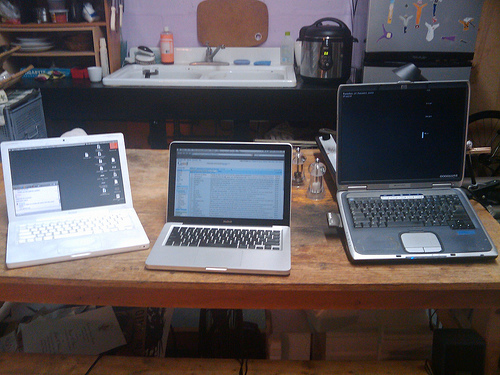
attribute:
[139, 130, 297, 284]
laptop — open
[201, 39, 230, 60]
faucet — silver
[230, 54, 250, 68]
soap — blue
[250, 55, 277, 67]
soap — blue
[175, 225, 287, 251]
keys — black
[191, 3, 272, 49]
cutting board — brown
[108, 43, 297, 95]
sink — white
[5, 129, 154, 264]
laptop — on, white, open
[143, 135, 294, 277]
laptop — on, gray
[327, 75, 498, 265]
laptop — gray, open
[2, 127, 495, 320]
surface — wooden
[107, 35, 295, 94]
sink — dirty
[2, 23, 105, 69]
shelf — brown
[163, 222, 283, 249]
keyboard — black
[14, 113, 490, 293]
countertop — silver, black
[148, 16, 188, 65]
bottle of soap — orange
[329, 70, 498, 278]
silver laptop — black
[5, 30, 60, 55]
plates on shelf — stack, white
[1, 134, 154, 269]
laptop computer — newer-looking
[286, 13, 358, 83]
rice cooker — high-quality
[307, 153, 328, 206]
glass salt shaker — fancy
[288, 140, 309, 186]
glass pepper shaker — fancy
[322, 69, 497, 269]
heavy computer — old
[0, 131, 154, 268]
mac laptop computer — newer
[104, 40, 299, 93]
double sink — white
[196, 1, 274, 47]
cutting board — small, wooden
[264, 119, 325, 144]
paper in trashcan — pile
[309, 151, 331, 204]
clear glass — salt, pepper, shakers